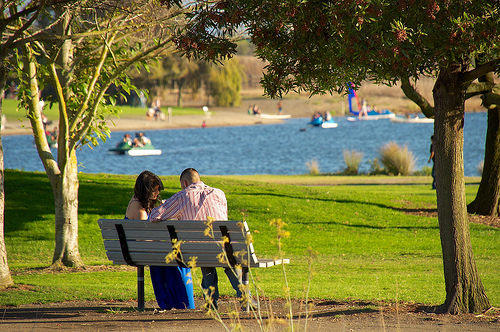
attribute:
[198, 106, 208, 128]
person — distant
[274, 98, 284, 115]
person — distant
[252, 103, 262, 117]
person — distant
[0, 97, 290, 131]
beach — distant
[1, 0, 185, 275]
tree — Large 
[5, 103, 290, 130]
beach — sandy 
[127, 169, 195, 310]
dress — blue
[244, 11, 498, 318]
tree — small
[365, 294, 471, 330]
dirt — brown 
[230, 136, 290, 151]
water — ripply, blue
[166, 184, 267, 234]
shirt — red , white 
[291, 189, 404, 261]
grass — green 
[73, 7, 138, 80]
tree branches — pictured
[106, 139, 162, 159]
boat — small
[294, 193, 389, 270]
grassy terrain — Green 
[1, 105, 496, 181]
water — blue 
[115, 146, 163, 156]
boat — distant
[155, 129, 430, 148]
water — clear, blue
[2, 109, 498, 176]
water — blue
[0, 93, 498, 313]
lawn — green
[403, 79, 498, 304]
trunk — brown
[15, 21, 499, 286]
park — white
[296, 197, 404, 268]
grass — very short, green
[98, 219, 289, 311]
bench — large, wooden, brown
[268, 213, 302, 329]
weed — tall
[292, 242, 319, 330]
weed — tall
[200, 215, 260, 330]
weed — tall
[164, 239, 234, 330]
weed — tall